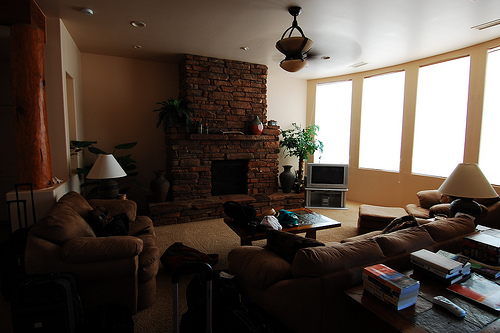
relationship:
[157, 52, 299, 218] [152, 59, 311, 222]
fireplace on wall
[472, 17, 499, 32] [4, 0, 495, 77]
vent on ceiling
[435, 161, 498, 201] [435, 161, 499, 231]
shade on lamp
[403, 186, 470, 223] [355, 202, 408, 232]
chair behind ottoman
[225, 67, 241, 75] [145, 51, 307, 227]
brick on fireplace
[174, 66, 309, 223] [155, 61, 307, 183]
brick on fireplace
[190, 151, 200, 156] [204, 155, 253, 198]
brick on fireplace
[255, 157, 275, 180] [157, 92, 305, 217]
red brick on fireplace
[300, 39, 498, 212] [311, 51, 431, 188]
frame on window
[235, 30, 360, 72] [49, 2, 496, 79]
fan on ceiling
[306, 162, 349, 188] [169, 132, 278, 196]
tv by fireplace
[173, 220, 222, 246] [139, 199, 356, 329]
carpet on floor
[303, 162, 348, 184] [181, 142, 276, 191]
tv by fireplace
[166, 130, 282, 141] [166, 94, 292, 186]
ledge on fireplace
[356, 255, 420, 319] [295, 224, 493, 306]
books sitting on a table